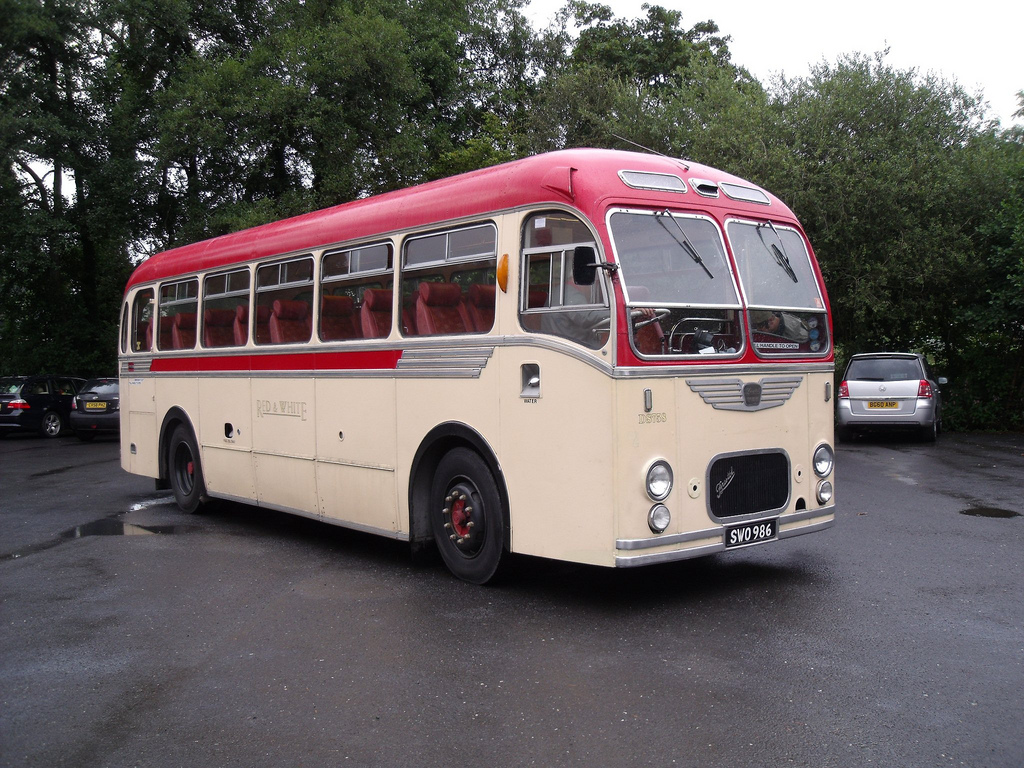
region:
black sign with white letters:
[724, 519, 783, 548]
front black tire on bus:
[421, 442, 499, 576]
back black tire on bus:
[160, 423, 205, 510]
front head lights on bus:
[640, 459, 676, 539]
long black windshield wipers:
[652, 200, 804, 284]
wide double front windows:
[607, 205, 833, 376]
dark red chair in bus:
[413, 282, 470, 337]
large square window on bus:
[400, 216, 496, 338]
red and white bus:
[198, 180, 771, 572]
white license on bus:
[716, 499, 786, 551]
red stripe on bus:
[125, 279, 449, 398]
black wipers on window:
[634, 206, 800, 317]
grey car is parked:
[807, 332, 967, 449]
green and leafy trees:
[649, 31, 988, 358]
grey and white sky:
[798, 7, 996, 103]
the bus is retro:
[126, 145, 835, 572]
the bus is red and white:
[107, 160, 838, 573]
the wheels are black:
[157, 416, 513, 591]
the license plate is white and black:
[707, 524, 790, 556]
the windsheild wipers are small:
[659, 208, 802, 284]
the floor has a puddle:
[13, 492, 195, 569]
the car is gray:
[849, 345, 933, 431]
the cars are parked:
[5, 370, 117, 438]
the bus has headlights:
[642, 432, 836, 527]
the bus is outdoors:
[119, 148, 837, 567]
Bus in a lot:
[95, 136, 880, 596]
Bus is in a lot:
[83, 128, 887, 625]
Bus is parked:
[96, 136, 849, 615]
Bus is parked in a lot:
[90, 133, 866, 628]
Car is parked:
[829, 342, 954, 448]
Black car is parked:
[1, 358, 101, 457]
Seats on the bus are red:
[112, 276, 666, 357]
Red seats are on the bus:
[125, 275, 698, 364]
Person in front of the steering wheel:
[526, 250, 667, 356]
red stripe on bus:
[146, 338, 421, 405]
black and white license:
[687, 513, 780, 542]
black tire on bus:
[397, 516, 516, 606]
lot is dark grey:
[400, 607, 543, 744]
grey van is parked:
[819, 314, 968, 457]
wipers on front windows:
[541, 215, 816, 317]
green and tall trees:
[61, 10, 602, 214]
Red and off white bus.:
[119, 145, 837, 591]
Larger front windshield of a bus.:
[609, 204, 745, 359]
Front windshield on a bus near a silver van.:
[724, 217, 829, 358]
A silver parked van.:
[839, 350, 945, 442]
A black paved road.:
[3, 433, 1022, 766]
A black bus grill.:
[708, 451, 791, 522]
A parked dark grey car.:
[68, 378, 125, 437]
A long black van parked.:
[0, 369, 90, 436]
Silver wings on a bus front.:
[685, 373, 804, 416]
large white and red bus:
[113, 143, 841, 605]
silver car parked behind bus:
[836, 344, 945, 447]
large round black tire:
[411, 427, 514, 584]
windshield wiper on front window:
[659, 208, 717, 285]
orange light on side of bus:
[486, 243, 515, 305]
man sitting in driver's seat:
[543, 258, 655, 357]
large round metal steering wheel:
[593, 294, 677, 339]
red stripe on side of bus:
[145, 347, 405, 382]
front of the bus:
[423, 120, 956, 582]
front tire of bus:
[331, 379, 594, 618]